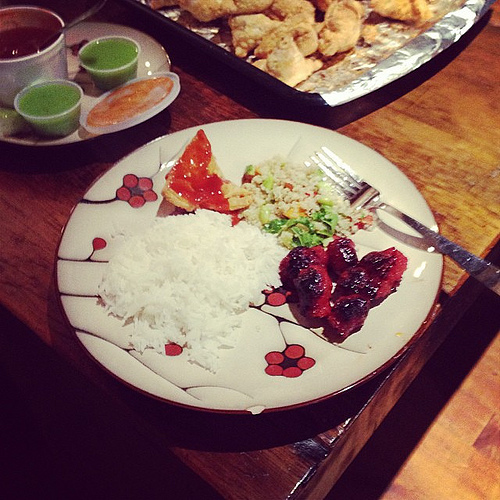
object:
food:
[149, 0, 465, 86]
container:
[13, 76, 84, 137]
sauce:
[0, 25, 55, 62]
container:
[0, 4, 67, 110]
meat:
[286, 239, 406, 343]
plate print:
[250, 286, 366, 378]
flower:
[265, 343, 314, 378]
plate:
[57, 119, 443, 415]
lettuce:
[262, 201, 338, 249]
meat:
[279, 236, 407, 337]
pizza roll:
[265, 35, 304, 81]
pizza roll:
[317, 0, 362, 57]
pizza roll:
[376, 0, 432, 20]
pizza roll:
[228, 14, 275, 58]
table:
[1, 2, 498, 498]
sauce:
[84, 75, 175, 125]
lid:
[78, 72, 181, 134]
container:
[77, 35, 140, 90]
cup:
[13, 78, 84, 139]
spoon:
[12, 0, 107, 57]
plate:
[0, 22, 172, 146]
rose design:
[116, 173, 157, 208]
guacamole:
[12, 77, 84, 137]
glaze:
[279, 245, 332, 318]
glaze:
[328, 296, 371, 338]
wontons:
[178, 0, 433, 83]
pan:
[146, 0, 462, 95]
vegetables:
[242, 153, 381, 251]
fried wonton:
[161, 129, 252, 212]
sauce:
[169, 130, 229, 208]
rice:
[95, 208, 288, 376]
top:
[74, 69, 181, 135]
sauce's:
[0, 13, 68, 69]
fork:
[303, 145, 500, 299]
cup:
[80, 36, 138, 87]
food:
[99, 129, 409, 359]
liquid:
[19, 85, 79, 119]